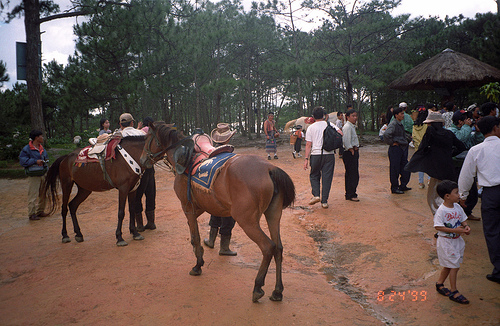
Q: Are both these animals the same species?
A: Yes, all the animals are horses.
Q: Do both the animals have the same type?
A: Yes, all the animals are horses.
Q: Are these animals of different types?
A: No, all the animals are horses.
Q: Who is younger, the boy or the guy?
A: The boy is younger than the guy.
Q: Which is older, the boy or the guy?
A: The guy is older than the boy.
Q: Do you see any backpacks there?
A: Yes, there is a backpack.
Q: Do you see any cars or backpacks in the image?
A: Yes, there is a backpack.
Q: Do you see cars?
A: No, there are no cars.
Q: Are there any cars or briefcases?
A: No, there are no cars or briefcases.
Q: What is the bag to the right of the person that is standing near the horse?
A: The bag is a backpack.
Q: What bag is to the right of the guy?
A: The bag is a backpack.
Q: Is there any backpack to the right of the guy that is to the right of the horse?
A: Yes, there is a backpack to the right of the guy.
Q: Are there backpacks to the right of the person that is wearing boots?
A: Yes, there is a backpack to the right of the guy.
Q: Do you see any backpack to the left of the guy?
A: No, the backpack is to the right of the guy.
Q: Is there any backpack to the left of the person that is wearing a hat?
A: No, the backpack is to the right of the guy.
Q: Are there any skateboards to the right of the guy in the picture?
A: No, there is a backpack to the right of the guy.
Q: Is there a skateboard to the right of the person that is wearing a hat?
A: No, there is a backpack to the right of the guy.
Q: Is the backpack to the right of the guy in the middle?
A: Yes, the backpack is to the right of the guy.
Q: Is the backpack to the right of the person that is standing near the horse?
A: Yes, the backpack is to the right of the guy.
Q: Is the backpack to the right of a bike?
A: No, the backpack is to the right of the guy.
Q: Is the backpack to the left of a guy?
A: No, the backpack is to the right of a guy.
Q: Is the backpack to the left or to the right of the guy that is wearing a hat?
A: The backpack is to the right of the guy.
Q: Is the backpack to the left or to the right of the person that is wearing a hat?
A: The backpack is to the right of the guy.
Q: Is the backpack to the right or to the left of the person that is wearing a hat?
A: The backpack is to the right of the guy.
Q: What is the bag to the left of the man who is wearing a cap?
A: The bag is a backpack.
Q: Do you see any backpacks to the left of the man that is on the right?
A: Yes, there is a backpack to the left of the man.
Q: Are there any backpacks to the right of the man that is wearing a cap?
A: No, the backpack is to the left of the man.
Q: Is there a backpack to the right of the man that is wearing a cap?
A: No, the backpack is to the left of the man.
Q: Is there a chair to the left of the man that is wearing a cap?
A: No, there is a backpack to the left of the man.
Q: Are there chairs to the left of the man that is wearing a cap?
A: No, there is a backpack to the left of the man.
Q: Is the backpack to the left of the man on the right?
A: Yes, the backpack is to the left of the man.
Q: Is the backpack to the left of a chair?
A: No, the backpack is to the left of the man.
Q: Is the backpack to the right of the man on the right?
A: No, the backpack is to the left of the man.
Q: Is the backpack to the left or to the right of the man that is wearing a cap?
A: The backpack is to the left of the man.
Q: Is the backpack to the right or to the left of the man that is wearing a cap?
A: The backpack is to the left of the man.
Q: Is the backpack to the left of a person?
A: Yes, the backpack is to the left of a person.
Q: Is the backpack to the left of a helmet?
A: No, the backpack is to the left of a person.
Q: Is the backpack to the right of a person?
A: No, the backpack is to the left of a person.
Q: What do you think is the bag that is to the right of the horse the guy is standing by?
A: The bag is a backpack.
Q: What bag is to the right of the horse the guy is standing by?
A: The bag is a backpack.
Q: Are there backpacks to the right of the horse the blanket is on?
A: Yes, there is a backpack to the right of the horse.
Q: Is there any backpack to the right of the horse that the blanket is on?
A: Yes, there is a backpack to the right of the horse.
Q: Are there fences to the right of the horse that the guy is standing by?
A: No, there is a backpack to the right of the horse.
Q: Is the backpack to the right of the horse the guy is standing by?
A: Yes, the backpack is to the right of the horse.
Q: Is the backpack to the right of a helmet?
A: No, the backpack is to the right of the horse.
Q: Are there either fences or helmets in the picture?
A: No, there are no fences or helmets.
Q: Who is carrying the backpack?
A: The man is carrying the backpack.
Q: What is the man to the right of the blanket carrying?
A: The man is carrying a backpack.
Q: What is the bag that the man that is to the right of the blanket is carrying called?
A: The bag is a backpack.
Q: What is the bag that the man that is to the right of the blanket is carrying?
A: The bag is a backpack.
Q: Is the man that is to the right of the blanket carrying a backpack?
A: Yes, the man is carrying a backpack.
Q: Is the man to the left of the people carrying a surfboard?
A: No, the man is carrying a backpack.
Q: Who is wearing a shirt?
A: The man is wearing a shirt.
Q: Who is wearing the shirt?
A: The man is wearing a shirt.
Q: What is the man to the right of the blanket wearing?
A: The man is wearing a shirt.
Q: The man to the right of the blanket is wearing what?
A: The man is wearing a shirt.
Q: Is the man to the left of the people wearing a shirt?
A: Yes, the man is wearing a shirt.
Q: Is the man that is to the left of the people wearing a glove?
A: No, the man is wearing a shirt.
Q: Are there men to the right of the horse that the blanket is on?
A: Yes, there is a man to the right of the horse.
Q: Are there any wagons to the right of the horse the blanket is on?
A: No, there is a man to the right of the horse.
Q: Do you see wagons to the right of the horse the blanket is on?
A: No, there is a man to the right of the horse.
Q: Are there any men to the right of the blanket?
A: Yes, there is a man to the right of the blanket.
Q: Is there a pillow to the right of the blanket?
A: No, there is a man to the right of the blanket.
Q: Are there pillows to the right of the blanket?
A: No, there is a man to the right of the blanket.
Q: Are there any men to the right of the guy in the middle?
A: Yes, there is a man to the right of the guy.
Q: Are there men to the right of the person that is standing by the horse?
A: Yes, there is a man to the right of the guy.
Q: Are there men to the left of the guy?
A: No, the man is to the right of the guy.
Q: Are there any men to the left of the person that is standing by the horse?
A: No, the man is to the right of the guy.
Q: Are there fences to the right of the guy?
A: No, there is a man to the right of the guy.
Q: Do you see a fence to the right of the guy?
A: No, there is a man to the right of the guy.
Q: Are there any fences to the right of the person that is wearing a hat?
A: No, there is a man to the right of the guy.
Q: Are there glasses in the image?
A: No, there are no glasses.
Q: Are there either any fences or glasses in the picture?
A: No, there are no glasses or fences.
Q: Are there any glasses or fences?
A: No, there are no glasses or fences.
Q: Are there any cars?
A: No, there are no cars.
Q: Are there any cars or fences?
A: No, there are no cars or fences.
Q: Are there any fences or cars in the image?
A: No, there are no cars or fences.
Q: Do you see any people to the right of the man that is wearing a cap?
A: Yes, there is a person to the right of the man.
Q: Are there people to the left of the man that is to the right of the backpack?
A: No, the person is to the right of the man.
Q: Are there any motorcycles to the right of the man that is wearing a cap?
A: No, there is a person to the right of the man.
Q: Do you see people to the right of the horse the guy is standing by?
A: Yes, there is a person to the right of the horse.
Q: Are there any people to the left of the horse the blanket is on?
A: No, the person is to the right of the horse.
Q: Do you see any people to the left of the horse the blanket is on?
A: No, the person is to the right of the horse.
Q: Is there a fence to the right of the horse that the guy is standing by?
A: No, there is a person to the right of the horse.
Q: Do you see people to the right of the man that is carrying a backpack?
A: Yes, there is a person to the right of the man.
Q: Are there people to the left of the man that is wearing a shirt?
A: No, the person is to the right of the man.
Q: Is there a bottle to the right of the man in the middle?
A: No, there is a person to the right of the man.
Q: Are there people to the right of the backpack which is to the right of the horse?
A: Yes, there is a person to the right of the backpack.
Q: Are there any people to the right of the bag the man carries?
A: Yes, there is a person to the right of the backpack.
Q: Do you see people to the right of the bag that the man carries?
A: Yes, there is a person to the right of the backpack.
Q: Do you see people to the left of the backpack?
A: No, the person is to the right of the backpack.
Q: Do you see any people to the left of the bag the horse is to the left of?
A: No, the person is to the right of the backpack.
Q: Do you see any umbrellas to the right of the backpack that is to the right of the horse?
A: No, there is a person to the right of the backpack.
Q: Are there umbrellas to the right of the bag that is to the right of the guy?
A: No, there is a person to the right of the backpack.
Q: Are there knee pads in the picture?
A: No, there are no knee pads.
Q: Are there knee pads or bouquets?
A: No, there are no knee pads or bouquets.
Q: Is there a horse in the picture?
A: Yes, there is a horse.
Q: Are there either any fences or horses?
A: Yes, there is a horse.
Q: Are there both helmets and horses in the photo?
A: No, there is a horse but no helmets.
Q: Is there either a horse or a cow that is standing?
A: Yes, the horse is standing.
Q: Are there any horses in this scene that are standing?
A: Yes, there is a horse that is standing.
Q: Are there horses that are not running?
A: Yes, there is a horse that is standing.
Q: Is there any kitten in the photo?
A: No, there are no kittens.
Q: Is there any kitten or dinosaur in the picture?
A: No, there are no kittens or dinosaurs.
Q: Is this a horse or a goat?
A: This is a horse.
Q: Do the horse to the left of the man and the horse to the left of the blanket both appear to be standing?
A: Yes, both the horse and the horse are standing.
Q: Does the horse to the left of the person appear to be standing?
A: Yes, the horse is standing.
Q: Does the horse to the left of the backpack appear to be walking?
A: No, the horse is standing.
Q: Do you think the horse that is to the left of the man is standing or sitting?
A: The horse is standing.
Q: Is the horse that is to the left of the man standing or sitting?
A: The horse is standing.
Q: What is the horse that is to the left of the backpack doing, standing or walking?
A: The horse is standing.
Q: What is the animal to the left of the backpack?
A: The animal is a horse.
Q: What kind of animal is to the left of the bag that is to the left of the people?
A: The animal is a horse.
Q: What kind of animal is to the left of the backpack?
A: The animal is a horse.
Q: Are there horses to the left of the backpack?
A: Yes, there is a horse to the left of the backpack.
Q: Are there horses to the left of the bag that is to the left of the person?
A: Yes, there is a horse to the left of the backpack.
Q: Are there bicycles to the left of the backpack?
A: No, there is a horse to the left of the backpack.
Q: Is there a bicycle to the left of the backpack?
A: No, there is a horse to the left of the backpack.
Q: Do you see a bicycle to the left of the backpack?
A: No, there is a horse to the left of the backpack.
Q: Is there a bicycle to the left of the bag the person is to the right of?
A: No, there is a horse to the left of the backpack.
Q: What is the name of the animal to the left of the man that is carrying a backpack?
A: The animal is a horse.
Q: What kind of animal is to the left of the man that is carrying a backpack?
A: The animal is a horse.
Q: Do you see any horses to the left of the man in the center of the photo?
A: Yes, there is a horse to the left of the man.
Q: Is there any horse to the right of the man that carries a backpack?
A: No, the horse is to the left of the man.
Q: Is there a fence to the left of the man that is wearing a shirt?
A: No, there is a horse to the left of the man.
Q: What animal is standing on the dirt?
A: The horse is standing on the dirt.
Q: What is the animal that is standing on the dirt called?
A: The animal is a horse.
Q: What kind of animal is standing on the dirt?
A: The animal is a horse.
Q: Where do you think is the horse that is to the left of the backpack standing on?
A: The horse is standing on the dirt.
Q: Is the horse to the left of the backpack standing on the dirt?
A: Yes, the horse is standing on the dirt.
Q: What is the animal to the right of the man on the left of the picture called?
A: The animal is a horse.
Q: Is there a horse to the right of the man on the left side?
A: Yes, there is a horse to the right of the man.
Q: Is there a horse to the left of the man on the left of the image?
A: No, the horse is to the right of the man.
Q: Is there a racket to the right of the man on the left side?
A: No, there is a horse to the right of the man.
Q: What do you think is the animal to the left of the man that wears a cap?
A: The animal is a horse.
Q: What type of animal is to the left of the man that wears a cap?
A: The animal is a horse.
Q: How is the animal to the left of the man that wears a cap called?
A: The animal is a horse.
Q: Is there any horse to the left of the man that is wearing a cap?
A: Yes, there is a horse to the left of the man.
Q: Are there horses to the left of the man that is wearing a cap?
A: Yes, there is a horse to the left of the man.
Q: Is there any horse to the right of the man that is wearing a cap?
A: No, the horse is to the left of the man.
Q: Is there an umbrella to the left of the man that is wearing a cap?
A: No, there is a horse to the left of the man.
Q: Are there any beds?
A: No, there are no beds.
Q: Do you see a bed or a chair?
A: No, there are no beds or chairs.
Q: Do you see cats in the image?
A: No, there are no cats.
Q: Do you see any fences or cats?
A: No, there are no cats or fences.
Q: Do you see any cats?
A: No, there are no cats.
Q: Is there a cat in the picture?
A: No, there are no cats.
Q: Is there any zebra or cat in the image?
A: No, there are no cats or zebras.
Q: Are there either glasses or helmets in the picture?
A: No, there are no glasses or helmets.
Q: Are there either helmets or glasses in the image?
A: No, there are no glasses or helmets.